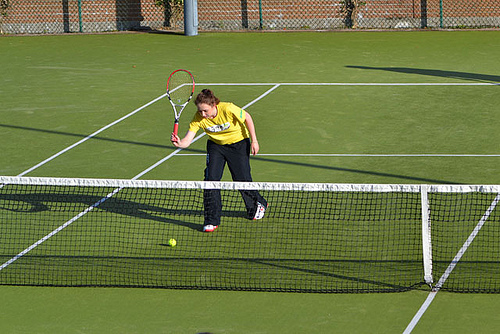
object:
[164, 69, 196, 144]
tennis racket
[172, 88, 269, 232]
woman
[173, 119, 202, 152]
arm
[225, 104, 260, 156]
arm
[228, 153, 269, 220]
leg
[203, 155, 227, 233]
leg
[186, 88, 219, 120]
head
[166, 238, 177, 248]
tennis ball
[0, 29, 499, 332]
ground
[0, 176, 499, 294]
net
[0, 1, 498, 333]
tennis court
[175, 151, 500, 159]
line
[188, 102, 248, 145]
shirt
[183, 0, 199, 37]
pole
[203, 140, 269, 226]
pants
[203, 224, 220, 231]
tennis shoe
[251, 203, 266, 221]
tennis shoe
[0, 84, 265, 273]
line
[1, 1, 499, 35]
wall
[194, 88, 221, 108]
hair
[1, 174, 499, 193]
trim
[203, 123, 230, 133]
logo